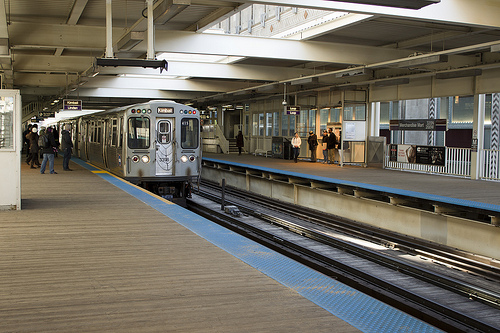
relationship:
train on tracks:
[74, 98, 217, 181] [247, 225, 304, 254]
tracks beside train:
[284, 205, 345, 240] [74, 98, 217, 181]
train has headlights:
[74, 98, 217, 181] [130, 149, 198, 166]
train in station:
[74, 98, 217, 181] [19, 9, 490, 327]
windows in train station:
[247, 113, 322, 133] [19, 9, 490, 327]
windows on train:
[81, 121, 120, 150] [74, 98, 217, 181]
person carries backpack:
[39, 122, 56, 175] [36, 133, 51, 150]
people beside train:
[27, 122, 82, 177] [74, 98, 217, 181]